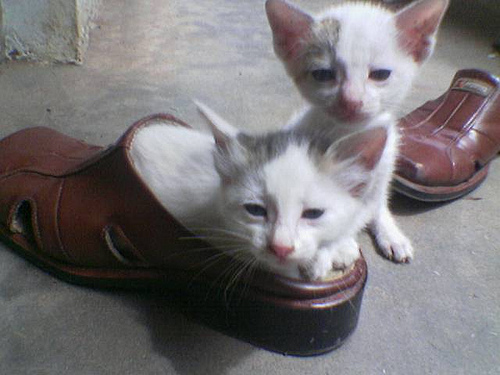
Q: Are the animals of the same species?
A: Yes, all the animals are cats.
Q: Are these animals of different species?
A: No, all the animals are cats.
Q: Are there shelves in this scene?
A: No, there are no shelves.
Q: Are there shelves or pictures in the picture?
A: No, there are no shelves or pictures.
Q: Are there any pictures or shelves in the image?
A: No, there are no shelves or pictures.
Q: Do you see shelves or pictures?
A: No, there are no shelves or pictures.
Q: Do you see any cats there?
A: Yes, there is a cat.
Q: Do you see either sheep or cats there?
A: Yes, there is a cat.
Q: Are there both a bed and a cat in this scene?
A: No, there is a cat but no beds.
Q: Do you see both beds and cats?
A: No, there is a cat but no beds.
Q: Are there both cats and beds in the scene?
A: No, there is a cat but no beds.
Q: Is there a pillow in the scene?
A: No, there are no pillows.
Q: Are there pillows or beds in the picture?
A: No, there are no pillows or beds.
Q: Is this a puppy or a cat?
A: This is a cat.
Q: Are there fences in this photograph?
A: No, there are no fences.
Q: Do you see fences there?
A: No, there are no fences.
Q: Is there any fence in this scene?
A: No, there are no fences.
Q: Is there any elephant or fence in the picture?
A: No, there are no fences or elephants.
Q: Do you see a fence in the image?
A: No, there are no fences.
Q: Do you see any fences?
A: No, there are no fences.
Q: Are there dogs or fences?
A: No, there are no fences or dogs.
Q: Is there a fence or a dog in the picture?
A: No, there are no fences or dogs.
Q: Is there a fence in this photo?
A: No, there are no fences.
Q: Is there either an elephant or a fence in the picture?
A: No, there are no fences or elephants.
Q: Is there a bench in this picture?
A: No, there are no benches.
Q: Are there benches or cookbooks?
A: No, there are no benches or cookbooks.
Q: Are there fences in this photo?
A: No, there are no fences.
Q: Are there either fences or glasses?
A: No, there are no fences or glasses.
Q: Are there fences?
A: No, there are no fences.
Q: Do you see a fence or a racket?
A: No, there are no fences or rackets.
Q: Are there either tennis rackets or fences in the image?
A: No, there are no fences or tennis rackets.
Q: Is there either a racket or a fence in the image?
A: No, there are no fences or rackets.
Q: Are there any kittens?
A: Yes, there is a kitten.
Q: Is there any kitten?
A: Yes, there is a kitten.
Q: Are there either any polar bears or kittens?
A: Yes, there is a kitten.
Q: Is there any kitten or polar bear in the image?
A: Yes, there is a kitten.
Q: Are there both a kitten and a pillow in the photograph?
A: No, there is a kitten but no pillows.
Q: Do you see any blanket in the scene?
A: No, there are no blankets.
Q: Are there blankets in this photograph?
A: No, there are no blankets.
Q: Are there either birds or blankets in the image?
A: No, there are no blankets or birds.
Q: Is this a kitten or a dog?
A: This is a kitten.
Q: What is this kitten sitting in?
A: The kitten is sitting in the shoe.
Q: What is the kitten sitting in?
A: The kitten is sitting in the shoe.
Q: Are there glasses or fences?
A: No, there are no fences or glasses.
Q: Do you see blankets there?
A: No, there are no blankets.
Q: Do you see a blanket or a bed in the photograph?
A: No, there are no blankets or beds.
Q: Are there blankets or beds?
A: No, there are no blankets or beds.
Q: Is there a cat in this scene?
A: Yes, there is a cat.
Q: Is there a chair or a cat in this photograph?
A: Yes, there is a cat.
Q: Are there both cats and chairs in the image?
A: No, there is a cat but no chairs.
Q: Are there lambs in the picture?
A: No, there are no lambs.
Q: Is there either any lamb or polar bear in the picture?
A: No, there are no lambs or polar bears.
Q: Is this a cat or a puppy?
A: This is a cat.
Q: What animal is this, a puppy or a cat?
A: This is a cat.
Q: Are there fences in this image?
A: No, there are no fences.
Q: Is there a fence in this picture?
A: No, there are no fences.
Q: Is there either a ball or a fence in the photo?
A: No, there are no fences or balls.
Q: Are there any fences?
A: No, there are no fences.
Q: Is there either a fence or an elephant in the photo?
A: No, there are no fences or elephants.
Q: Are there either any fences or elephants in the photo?
A: No, there are no fences or elephants.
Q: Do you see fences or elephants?
A: No, there are no fences or elephants.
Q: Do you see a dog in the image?
A: No, there are no dogs.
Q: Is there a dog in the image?
A: No, there are no dogs.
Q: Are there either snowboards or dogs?
A: No, there are no dogs or snowboards.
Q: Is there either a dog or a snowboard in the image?
A: No, there are no dogs or snowboards.